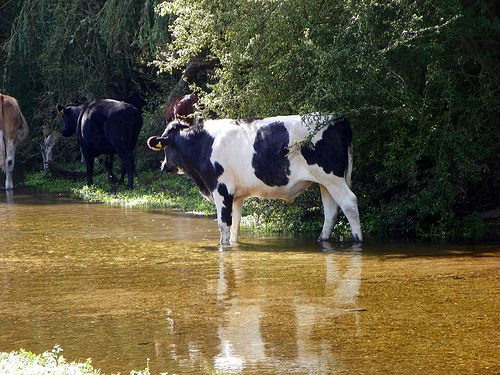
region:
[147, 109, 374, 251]
The cow is spotted.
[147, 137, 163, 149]
Cow's ear is tagged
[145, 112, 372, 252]
The cow is black and white.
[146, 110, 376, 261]
The cow is wading in water.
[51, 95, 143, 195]
The cow is black.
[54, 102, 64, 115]
Cow's ear is tagged.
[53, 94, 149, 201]
Cow is walking on the bank.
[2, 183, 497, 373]
The water is shallow.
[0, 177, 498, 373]
The water is very still and calm.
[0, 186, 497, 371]
The stretch of water is placid.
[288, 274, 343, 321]
part of a swamp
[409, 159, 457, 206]
part of some leaves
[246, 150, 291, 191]
stomach of a cow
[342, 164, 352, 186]
tail of a cow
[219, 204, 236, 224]
part of a leg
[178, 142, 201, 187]
neck of a cow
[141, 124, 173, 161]
ear of a cow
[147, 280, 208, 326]
part of a surface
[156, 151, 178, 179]
part of a mouth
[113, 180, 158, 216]
part of a shore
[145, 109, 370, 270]
this is a cow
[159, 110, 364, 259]
the cow is white and black in color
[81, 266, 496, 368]
water is on the place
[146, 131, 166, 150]
this is the ear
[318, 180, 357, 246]
the legs are short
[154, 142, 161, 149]
the peg is yellow in color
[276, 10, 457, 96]
these are green leaves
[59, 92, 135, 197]
the cow is fat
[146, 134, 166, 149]
the ear is big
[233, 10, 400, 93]
the leaves are green in color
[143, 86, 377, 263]
Black and white bull in the water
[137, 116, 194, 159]
The bull has horns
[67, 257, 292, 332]
The water is muddy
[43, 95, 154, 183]
Black bull is standing on green grass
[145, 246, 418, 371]
Reflection of bull is in the water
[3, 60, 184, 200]
Several bills are keeping cool in the shade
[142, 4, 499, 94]
Brush is pretty and green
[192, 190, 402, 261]
All four feet of the bull are in the water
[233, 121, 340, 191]
There are black spots on the bull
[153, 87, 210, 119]
Brown bull hinding in the bushes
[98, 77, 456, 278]
a black and white cow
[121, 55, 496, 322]
a cow standing by itself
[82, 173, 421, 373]
a cow standing on water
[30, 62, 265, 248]
cows drinking water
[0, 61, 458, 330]
cows absorbing the sun rays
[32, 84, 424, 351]
yellow dirty water with cow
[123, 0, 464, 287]
cows in nature with trees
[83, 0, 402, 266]
cows surrounded by trees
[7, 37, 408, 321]
different colored cows standing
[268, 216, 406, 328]
reflection of cow's legs